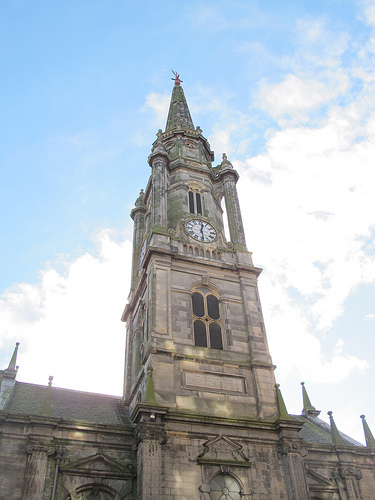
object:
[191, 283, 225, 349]
window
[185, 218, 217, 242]
clock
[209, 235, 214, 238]
roman numerals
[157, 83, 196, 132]
roof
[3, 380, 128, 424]
roof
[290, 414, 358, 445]
roof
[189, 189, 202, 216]
window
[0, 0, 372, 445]
sky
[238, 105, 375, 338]
clouds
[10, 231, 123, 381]
clouds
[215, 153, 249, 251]
column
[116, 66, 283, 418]
tower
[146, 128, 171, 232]
column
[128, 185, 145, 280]
column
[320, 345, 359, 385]
clouds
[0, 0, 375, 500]
scene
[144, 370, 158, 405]
moss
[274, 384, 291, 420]
moss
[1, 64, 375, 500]
building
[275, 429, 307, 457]
details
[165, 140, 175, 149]
details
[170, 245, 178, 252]
details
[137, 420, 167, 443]
details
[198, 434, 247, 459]
details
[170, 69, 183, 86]
statue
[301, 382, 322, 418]
spire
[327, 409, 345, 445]
spire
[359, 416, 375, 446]
spire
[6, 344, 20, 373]
spire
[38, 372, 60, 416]
spire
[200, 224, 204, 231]
hands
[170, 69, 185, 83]
weathervane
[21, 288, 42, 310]
clouds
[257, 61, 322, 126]
clouds